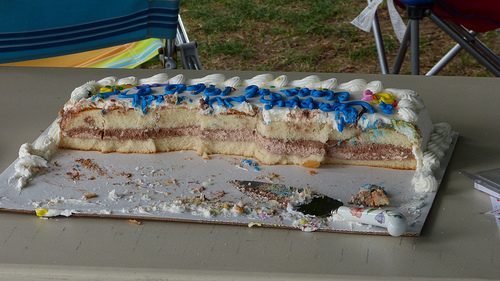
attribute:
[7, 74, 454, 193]
cake — existing, half eaten, delicious, cut, long, birthday cake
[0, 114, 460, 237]
sheet — white, cardboard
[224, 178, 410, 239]
cake cutter — in front, sharp, covered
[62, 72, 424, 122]
frosting — blue, white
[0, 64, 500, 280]
table — white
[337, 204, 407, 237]
handle — decorated, pink, floral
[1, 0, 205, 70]
picnic chair — fold up, blue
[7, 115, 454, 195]
frosting — white, piped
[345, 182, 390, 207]
crumb — colorful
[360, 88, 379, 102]
icing — pink